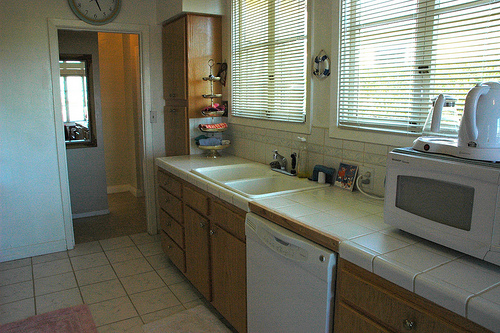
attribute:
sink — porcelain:
[187, 158, 332, 201]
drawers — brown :
[151, 165, 188, 277]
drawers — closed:
[153, 168, 184, 269]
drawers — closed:
[331, 280, 460, 331]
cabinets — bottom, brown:
[151, 203, 248, 304]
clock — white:
[62, 2, 129, 27]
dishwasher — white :
[247, 202, 336, 331]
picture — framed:
[325, 152, 358, 188]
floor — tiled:
[0, 231, 235, 331]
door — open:
[42, 21, 162, 249]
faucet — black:
[282, 147, 303, 177]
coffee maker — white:
[457, 71, 492, 158]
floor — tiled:
[4, 229, 208, 331]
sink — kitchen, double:
[193, 149, 323, 203]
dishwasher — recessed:
[238, 212, 332, 327]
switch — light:
[148, 103, 165, 132]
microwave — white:
[381, 144, 497, 268]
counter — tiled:
[152, 146, 499, 331]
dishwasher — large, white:
[234, 207, 336, 331]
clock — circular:
[67, 0, 120, 22]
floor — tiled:
[2, 216, 228, 331]